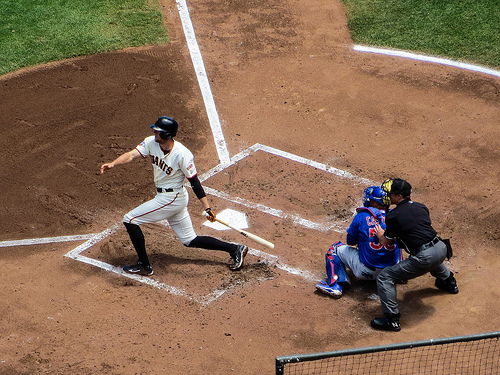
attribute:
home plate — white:
[207, 209, 251, 232]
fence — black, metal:
[271, 333, 499, 373]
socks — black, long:
[126, 222, 159, 270]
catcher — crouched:
[322, 181, 397, 294]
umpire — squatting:
[378, 180, 463, 322]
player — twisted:
[96, 117, 249, 275]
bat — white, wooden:
[205, 209, 283, 253]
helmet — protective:
[149, 117, 181, 139]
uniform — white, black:
[132, 138, 199, 240]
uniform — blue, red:
[327, 211, 398, 274]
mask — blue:
[358, 186, 371, 207]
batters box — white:
[195, 145, 380, 238]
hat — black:
[383, 178, 412, 197]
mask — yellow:
[379, 180, 391, 210]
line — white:
[171, 3, 234, 152]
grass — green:
[1, 2, 165, 56]